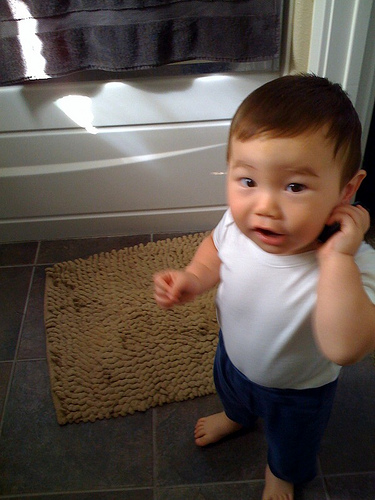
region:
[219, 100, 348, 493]
A Cute young baby standing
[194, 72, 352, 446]
A Cute young baby on phone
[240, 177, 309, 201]
Cute little clear eyes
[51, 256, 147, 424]
Brown door mat on the floor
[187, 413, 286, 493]
Thiny little naked feet in the ground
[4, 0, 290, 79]
A black towel hanging on the bathroom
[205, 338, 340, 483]
Nevy blue fitting trousers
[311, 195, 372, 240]
A small black cellphone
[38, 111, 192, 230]
White well vanished bathroom walls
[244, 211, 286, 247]
A smiling little mouth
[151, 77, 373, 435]
A young baby boy standing in the bathroom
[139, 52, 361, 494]
A baby boy standing near a bathtub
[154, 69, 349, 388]
An Asian baby touching his ear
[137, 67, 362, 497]
A cute baby looking up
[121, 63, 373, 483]
An Asian baby in the bathroom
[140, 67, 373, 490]
An Asian baby boy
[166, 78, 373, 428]
A baby boy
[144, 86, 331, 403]
An Asian baby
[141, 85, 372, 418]
A happy baby boy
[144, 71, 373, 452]
An Asian baby boy standing on a tiled floor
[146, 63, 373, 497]
little Asian baby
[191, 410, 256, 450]
little baby bare feet on tile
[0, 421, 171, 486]
dark color floor tile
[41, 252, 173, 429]
tan bathroom rug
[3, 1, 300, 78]
Navy hanging towel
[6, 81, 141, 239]
white tub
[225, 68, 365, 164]
Dark brown hair on baby boy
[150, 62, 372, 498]
Cute baby boy touching ear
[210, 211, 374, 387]
white baby tee shirt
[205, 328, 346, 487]
baby's blue pants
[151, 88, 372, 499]
little boy standing in the bathroom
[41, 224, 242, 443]
fuzzy bath mat on the ground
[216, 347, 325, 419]
shirt is tucked in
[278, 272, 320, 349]
wrinkles on the shirt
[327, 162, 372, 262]
hand is by ear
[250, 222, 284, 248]
mouth is open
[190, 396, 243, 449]
no shoe on foot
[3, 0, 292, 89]
towel hanging over the tub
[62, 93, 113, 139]
light shining on the tub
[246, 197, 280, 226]
small nose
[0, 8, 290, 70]
towel is dark grey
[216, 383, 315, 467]
boys pants are blue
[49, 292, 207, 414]
rug is on the ground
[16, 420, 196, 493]
the floor is tiled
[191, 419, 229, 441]
child has no shoes on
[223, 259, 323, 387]
child wearing a white shirt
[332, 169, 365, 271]
hand is on the child's ear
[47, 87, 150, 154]
sunlight reflection on the wall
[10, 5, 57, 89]
reflection of sun on towel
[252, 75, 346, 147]
child has short brown hair